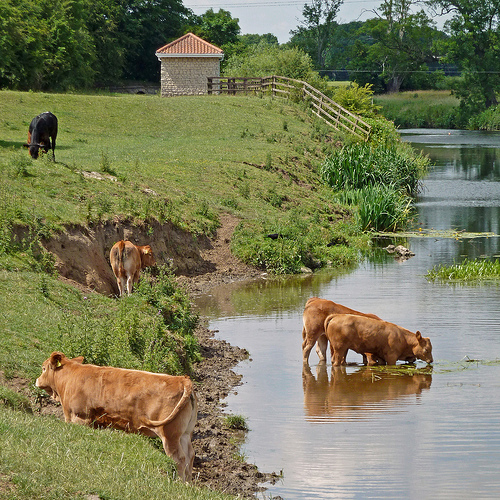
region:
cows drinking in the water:
[301, 295, 438, 390]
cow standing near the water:
[26, 346, 204, 470]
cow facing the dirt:
[100, 230, 162, 287]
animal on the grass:
[16, 104, 70, 163]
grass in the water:
[378, 355, 435, 382]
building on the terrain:
[148, 23, 240, 105]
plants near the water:
[337, 140, 400, 225]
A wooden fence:
[203, 68, 375, 149]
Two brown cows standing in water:
[294, 292, 441, 379]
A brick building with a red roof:
[151, 27, 229, 100]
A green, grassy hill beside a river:
[3, 88, 417, 499]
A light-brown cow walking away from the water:
[31, 346, 200, 480]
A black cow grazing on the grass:
[23, 109, 63, 166]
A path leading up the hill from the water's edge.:
[198, 194, 261, 283]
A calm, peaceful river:
[188, 120, 498, 497]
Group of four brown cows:
[28, 235, 440, 485]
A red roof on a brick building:
[154, 26, 225, 59]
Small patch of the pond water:
[337, 408, 382, 449]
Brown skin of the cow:
[86, 376, 119, 398]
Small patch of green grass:
[159, 116, 189, 152]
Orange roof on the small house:
[174, 35, 202, 54]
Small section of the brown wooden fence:
[218, 77, 257, 92]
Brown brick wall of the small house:
[168, 68, 191, 91]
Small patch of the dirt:
[207, 358, 222, 385]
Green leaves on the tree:
[363, 45, 389, 62]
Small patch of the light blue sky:
[261, 15, 286, 33]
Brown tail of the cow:
[147, 392, 199, 423]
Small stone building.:
[157, 29, 227, 95]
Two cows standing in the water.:
[295, 284, 437, 377]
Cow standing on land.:
[35, 344, 203, 484]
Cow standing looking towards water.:
[108, 239, 157, 301]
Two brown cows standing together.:
[300, 289, 439, 371]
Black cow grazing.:
[22, 108, 62, 163]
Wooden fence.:
[204, 68, 376, 146]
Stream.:
[183, 125, 498, 499]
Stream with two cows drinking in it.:
[190, 112, 498, 499]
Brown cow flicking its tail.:
[34, 348, 203, 484]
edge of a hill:
[271, 458, 279, 472]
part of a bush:
[420, 278, 430, 286]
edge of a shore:
[194, 353, 195, 357]